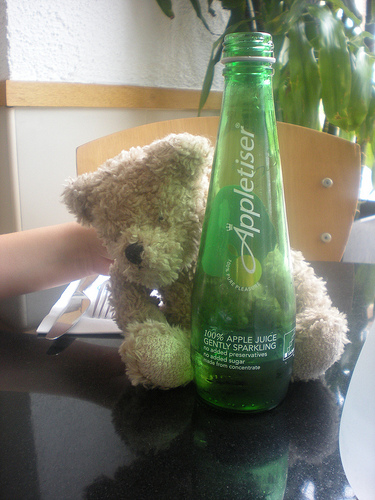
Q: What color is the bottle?
A: Green.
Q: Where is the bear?
A: Behind the bottle.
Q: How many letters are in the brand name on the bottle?
A: Ten.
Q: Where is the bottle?
A: On the table.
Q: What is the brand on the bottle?
A: Appletiser.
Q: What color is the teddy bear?
A: Brown.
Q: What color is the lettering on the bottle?
A: White.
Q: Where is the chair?
A: Behind the table.